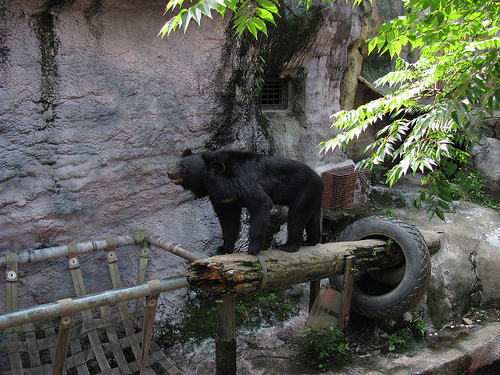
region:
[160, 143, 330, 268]
a black bear standing on a log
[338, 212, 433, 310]
a black rubber tire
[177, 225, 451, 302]
a wood log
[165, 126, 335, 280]
a bear on a log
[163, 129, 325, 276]
a bear standing on a log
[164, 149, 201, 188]
a bear with its mouth open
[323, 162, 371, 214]
a metal basket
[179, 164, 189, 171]
The bears eye is black.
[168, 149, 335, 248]
The bear is large.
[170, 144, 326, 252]
The bear has black fur.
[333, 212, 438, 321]
The tire is on the tree trunk.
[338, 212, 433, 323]
The tire is black in color.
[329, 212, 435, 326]
The tire is round.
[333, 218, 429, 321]
The tire is round.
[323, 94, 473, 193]
The sun is shining on the tree leaves.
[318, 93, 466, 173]
The leaves are green in color.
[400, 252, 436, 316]
a black rubber tire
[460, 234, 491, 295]
a crack in the rock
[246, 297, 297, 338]
plants in the ground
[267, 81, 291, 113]
bars in the wall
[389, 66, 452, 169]
a leaf on a tree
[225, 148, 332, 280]
a bear on a log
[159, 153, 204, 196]
a bears red tongue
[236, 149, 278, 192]
black fur on a bear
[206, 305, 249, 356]
a post holding a log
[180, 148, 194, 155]
The left ear of the bear.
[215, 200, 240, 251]
The front left leg of the bear.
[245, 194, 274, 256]
The front right leg of the bear.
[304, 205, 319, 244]
The back left leg of the bear.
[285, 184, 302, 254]
The back right leg of the bear.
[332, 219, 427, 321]
The black tire around the log.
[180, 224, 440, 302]
The log the bear is standing on.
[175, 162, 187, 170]
The eyes of the bear.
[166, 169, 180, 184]
The nose and mouth area of the bear.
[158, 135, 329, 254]
black bear standing on a log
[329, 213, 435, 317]
old tire around a log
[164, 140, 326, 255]
black bear held in captivity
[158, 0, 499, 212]
overhanging branches of a tree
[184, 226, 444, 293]
old log hanging horizontally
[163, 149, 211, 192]
head of a black bear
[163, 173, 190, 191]
mouth of a black bear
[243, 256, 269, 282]
leaves on the log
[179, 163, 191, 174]
left eye of the black bear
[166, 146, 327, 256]
Captive black bear in enclosure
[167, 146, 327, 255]
Black bear standing on elevated log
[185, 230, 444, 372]
Large horizontal log elevated on posts